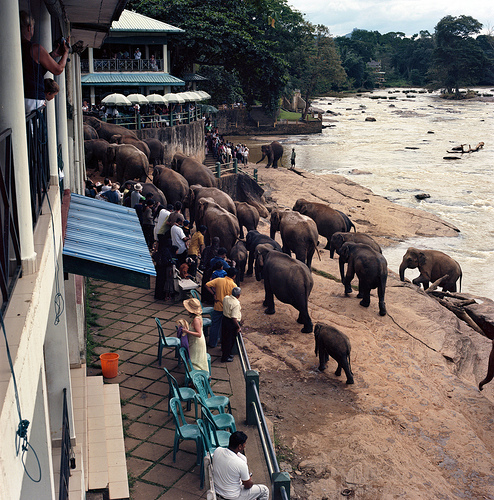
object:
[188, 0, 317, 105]
leaves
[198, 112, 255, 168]
staircase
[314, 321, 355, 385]
elephant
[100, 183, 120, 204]
they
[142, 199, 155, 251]
they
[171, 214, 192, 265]
they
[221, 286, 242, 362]
they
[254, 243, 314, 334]
elephant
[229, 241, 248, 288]
elephant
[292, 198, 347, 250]
elephant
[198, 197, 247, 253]
elephant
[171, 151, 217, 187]
elephant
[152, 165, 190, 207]
elephant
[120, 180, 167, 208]
elephant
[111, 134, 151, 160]
elephant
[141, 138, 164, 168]
elephant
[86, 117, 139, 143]
elephant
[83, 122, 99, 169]
elephant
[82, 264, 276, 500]
patio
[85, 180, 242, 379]
people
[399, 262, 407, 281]
trunk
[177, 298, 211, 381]
woman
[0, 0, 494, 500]
photo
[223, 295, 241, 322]
shirt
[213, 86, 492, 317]
water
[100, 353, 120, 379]
basket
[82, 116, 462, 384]
elephants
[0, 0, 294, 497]
town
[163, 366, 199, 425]
chair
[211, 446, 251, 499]
shirt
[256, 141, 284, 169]
elephant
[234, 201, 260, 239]
elephant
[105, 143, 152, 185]
elephant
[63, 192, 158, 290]
awning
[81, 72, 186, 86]
awning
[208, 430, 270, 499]
man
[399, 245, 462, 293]
elephant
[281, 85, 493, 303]
river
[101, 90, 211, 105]
group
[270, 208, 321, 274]
elephant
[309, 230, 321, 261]
tail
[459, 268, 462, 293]
tail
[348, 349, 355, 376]
tail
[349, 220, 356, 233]
tail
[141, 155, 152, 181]
tail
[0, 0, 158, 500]
building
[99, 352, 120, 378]
bucket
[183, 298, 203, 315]
hat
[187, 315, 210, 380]
dress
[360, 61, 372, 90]
leaves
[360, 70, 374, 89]
tree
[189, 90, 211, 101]
umbrellas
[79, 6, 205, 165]
building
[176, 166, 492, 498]
rocks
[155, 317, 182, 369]
blue chairs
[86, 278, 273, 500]
sidewalk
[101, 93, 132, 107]
umbrella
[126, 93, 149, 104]
umbrella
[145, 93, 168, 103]
umbrella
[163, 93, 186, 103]
umbrella